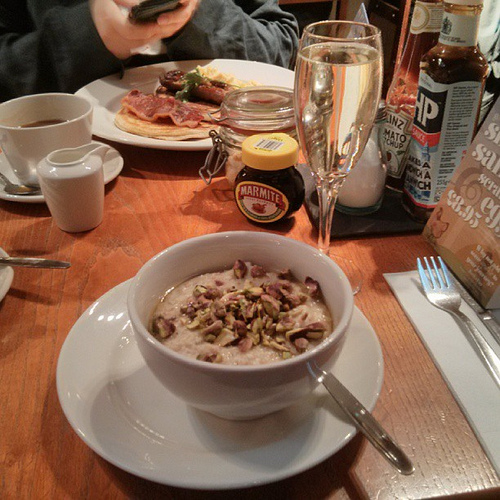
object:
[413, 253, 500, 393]
fork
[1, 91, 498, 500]
table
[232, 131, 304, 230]
marmite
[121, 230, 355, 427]
bowl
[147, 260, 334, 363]
soup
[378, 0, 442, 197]
ketchup bottle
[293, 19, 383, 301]
wine glass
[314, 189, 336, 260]
stem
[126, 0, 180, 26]
cellphone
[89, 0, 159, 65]
hand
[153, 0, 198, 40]
hand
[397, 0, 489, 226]
steak sauce bottle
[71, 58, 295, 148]
plate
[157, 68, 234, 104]
food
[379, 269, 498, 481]
napkin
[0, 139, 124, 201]
saucer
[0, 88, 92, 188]
cup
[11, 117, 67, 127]
coffee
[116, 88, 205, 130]
bacon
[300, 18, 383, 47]
top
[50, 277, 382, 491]
plate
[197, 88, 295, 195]
sugar holder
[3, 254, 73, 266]
utensil handle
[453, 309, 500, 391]
handle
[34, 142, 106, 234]
creamer dish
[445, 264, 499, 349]
knife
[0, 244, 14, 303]
plate